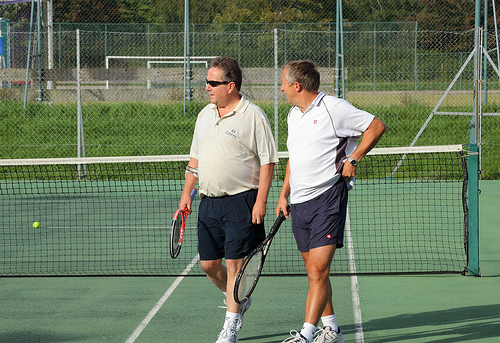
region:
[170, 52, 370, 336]
Peoples standing in the tennis court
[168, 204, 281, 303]
Peoples holding the tennis racket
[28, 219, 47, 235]
Tennis ball in the tennis court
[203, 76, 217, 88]
A person wearing goggles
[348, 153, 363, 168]
A person wearing wrist watch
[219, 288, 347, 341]
Peoples wearing pair of shoes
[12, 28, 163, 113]
Metal post with fencing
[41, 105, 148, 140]
Green color grass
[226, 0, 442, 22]
Lot of trees with it branches and leaves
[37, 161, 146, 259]
tennis net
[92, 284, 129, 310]
this is the ground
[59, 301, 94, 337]
the ground is green in color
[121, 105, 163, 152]
this is the grass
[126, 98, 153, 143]
the grass is green in color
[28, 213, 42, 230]
this is a ball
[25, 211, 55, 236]
the ball is in the air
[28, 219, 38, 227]
the ball is green in color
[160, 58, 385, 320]
these are two people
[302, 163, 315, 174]
the t-shirt is white in color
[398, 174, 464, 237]
this is a net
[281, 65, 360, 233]
this is a man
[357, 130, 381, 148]
the man is light skinned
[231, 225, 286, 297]
this is a racket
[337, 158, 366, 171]
this is a watch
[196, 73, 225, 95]
this is a spectacle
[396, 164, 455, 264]
this is a net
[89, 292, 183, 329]
this is the playing ground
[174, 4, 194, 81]
this is a pole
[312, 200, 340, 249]
this is a short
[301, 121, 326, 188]
this is a t shirt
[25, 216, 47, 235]
this is a tennis ball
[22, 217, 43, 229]
the ball is green in color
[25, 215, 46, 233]
the ball is small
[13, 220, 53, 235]
the ball is in the air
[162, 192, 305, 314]
these are some rackets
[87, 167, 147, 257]
this is a net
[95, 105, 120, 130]
this is the grass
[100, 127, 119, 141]
the grass is green in color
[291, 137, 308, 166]
the t-shirt is white in color